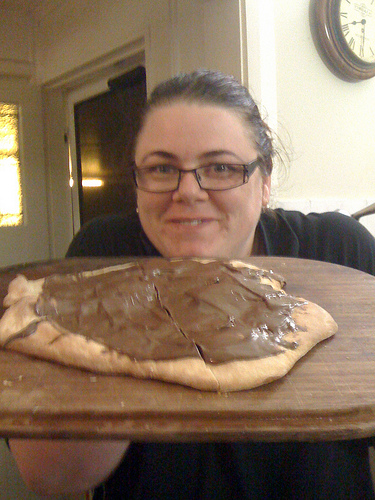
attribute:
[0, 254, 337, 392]
crust — pizza-like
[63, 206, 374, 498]
shirt — black, dark colored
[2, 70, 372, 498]
woman — young, smiling, dark haired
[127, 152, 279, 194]
glasses — brown, framed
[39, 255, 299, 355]
spread — chocolate, dark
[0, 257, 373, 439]
platter — serving, wooden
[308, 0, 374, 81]
clock — wood framed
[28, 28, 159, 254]
door frame — white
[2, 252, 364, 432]
plate — wooden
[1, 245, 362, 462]
plate — wooden